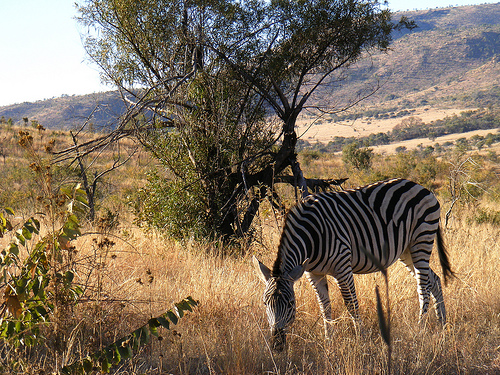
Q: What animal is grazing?
A: Zebra.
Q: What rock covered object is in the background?
A: Mountainside.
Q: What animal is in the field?
A: Zebra.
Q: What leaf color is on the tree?
A: Green.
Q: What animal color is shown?
A: Black and white.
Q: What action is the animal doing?
A: Eating.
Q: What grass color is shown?
A: Yellow and tall.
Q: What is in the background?
A: A large mountain is.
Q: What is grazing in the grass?
A: A zebra is grazing.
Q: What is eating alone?
A: A zebra is eating alone.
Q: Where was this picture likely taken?
A: Africa.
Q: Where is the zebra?
A: In the grass.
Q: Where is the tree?
A: Behind the zebra.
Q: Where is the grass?
A: On the ground.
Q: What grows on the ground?
A: Grass.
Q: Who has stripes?
A: The zebra.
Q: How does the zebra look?
A: Black and white.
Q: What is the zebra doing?
A: Eating.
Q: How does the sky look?
A: Clear.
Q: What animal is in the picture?
A: Zebra.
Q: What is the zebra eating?
A: Grass.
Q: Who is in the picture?
A: No one.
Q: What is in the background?
A: Mountain.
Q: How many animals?
A: 1.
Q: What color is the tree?
A: Green.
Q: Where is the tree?
A: Behind zebra.